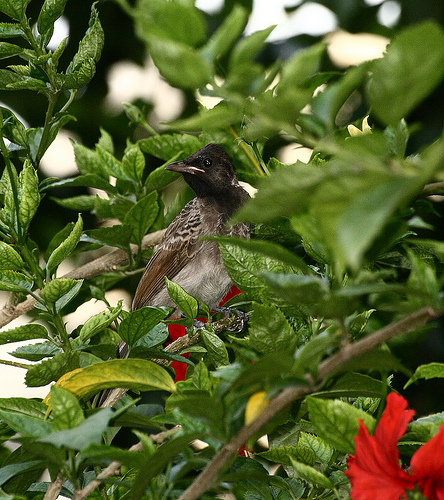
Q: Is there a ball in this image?
A: No, there are no balls.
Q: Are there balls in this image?
A: No, there are no balls.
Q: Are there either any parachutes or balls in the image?
A: No, there are no balls or parachutes.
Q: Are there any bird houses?
A: No, there are no bird houses.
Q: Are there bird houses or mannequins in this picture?
A: No, there are no bird houses or mannequins.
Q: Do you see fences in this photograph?
A: No, there are no fences.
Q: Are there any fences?
A: No, there are no fences.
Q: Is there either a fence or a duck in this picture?
A: No, there are no fences or ducks.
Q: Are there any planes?
A: No, there are no planes.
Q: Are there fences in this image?
A: No, there are no fences.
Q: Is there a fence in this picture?
A: No, there are no fences.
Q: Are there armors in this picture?
A: No, there are no armors.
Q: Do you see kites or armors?
A: No, there are no armors or kites.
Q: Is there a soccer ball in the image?
A: No, there are no soccer balls.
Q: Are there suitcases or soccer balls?
A: No, there are no soccer balls or suitcases.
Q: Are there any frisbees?
A: No, there are no frisbees.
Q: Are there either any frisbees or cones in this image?
A: No, there are no frisbees or cones.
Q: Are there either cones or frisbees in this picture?
A: No, there are no frisbees or cones.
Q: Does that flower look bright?
A: Yes, the flower is bright.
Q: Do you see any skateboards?
A: No, there are no skateboards.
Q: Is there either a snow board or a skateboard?
A: No, there are no skateboards or snowboards.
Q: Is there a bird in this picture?
A: Yes, there is a bird.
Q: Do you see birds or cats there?
A: Yes, there is a bird.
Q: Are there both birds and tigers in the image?
A: No, there is a bird but no tigers.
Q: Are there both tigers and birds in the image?
A: No, there is a bird but no tigers.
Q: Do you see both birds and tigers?
A: No, there is a bird but no tigers.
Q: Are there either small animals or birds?
A: Yes, there is a small bird.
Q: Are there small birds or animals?
A: Yes, there is a small bird.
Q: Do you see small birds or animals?
A: Yes, there is a small bird.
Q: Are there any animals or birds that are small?
A: Yes, the bird is small.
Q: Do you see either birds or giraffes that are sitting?
A: Yes, the bird is sitting.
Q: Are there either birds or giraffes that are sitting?
A: Yes, the bird is sitting.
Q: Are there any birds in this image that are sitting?
A: Yes, there is a bird that is sitting.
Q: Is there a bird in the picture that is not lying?
A: Yes, there is a bird that is sitting.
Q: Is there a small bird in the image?
A: Yes, there is a small bird.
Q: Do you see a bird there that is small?
A: Yes, there is a bird that is small.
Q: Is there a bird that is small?
A: Yes, there is a bird that is small.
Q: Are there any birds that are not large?
A: Yes, there is a small bird.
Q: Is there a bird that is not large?
A: Yes, there is a small bird.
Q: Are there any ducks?
A: No, there are no ducks.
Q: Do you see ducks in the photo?
A: No, there are no ducks.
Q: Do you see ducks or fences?
A: No, there are no ducks or fences.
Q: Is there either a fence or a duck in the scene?
A: No, there are no ducks or fences.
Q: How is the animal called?
A: The animal is a bird.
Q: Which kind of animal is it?
A: The animal is a bird.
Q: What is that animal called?
A: This is a bird.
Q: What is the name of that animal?
A: This is a bird.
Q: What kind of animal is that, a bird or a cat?
A: This is a bird.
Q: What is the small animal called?
A: The animal is a bird.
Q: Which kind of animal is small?
A: The animal is a bird.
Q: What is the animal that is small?
A: The animal is a bird.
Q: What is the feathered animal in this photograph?
A: The animal is a bird.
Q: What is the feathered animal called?
A: The animal is a bird.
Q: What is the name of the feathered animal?
A: The animal is a bird.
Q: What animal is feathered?
A: The animal is a bird.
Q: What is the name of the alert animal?
A: The animal is a bird.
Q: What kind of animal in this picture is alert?
A: The animal is a bird.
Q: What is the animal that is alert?
A: The animal is a bird.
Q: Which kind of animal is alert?
A: The animal is a bird.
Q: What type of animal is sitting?
A: The animal is a bird.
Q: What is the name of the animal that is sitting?
A: The animal is a bird.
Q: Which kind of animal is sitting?
A: The animal is a bird.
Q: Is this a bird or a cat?
A: This is a bird.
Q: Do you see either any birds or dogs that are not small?
A: No, there is a bird but it is small.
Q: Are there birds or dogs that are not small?
A: No, there is a bird but it is small.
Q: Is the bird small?
A: Yes, the bird is small.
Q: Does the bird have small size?
A: Yes, the bird is small.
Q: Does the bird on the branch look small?
A: Yes, the bird is small.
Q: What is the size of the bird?
A: The bird is small.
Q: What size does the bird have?
A: The bird has small size.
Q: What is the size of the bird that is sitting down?
A: The bird is small.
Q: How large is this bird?
A: The bird is small.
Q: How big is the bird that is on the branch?
A: The bird is small.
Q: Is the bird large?
A: No, the bird is small.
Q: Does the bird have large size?
A: No, the bird is small.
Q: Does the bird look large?
A: No, the bird is small.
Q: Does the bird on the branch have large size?
A: No, the bird is small.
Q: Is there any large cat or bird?
A: No, there is a bird but it is small.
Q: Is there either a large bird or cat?
A: No, there is a bird but it is small.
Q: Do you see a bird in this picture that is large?
A: No, there is a bird but it is small.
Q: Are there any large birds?
A: No, there is a bird but it is small.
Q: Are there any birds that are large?
A: No, there is a bird but it is small.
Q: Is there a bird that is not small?
A: No, there is a bird but it is small.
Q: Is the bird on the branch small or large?
A: The bird is small.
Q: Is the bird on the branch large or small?
A: The bird is small.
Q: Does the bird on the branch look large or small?
A: The bird is small.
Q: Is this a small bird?
A: Yes, this is a small bird.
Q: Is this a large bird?
A: No, this is a small bird.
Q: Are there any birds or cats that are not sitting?
A: No, there is a bird but it is sitting.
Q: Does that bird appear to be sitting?
A: Yes, the bird is sitting.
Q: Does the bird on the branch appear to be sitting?
A: Yes, the bird is sitting.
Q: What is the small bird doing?
A: The bird is sitting.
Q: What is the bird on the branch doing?
A: The bird is sitting.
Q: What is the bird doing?
A: The bird is sitting.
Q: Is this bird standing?
A: No, the bird is sitting.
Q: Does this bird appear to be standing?
A: No, the bird is sitting.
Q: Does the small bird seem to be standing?
A: No, the bird is sitting.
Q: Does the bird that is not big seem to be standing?
A: No, the bird is sitting.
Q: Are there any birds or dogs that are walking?
A: No, there is a bird but it is sitting.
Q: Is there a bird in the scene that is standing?
A: No, there is a bird but it is sitting.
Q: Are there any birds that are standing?
A: No, there is a bird but it is sitting.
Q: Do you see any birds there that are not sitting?
A: No, there is a bird but it is sitting.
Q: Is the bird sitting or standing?
A: The bird is sitting.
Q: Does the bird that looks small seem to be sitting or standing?
A: The bird is sitting.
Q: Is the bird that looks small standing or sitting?
A: The bird is sitting.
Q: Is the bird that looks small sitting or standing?
A: The bird is sitting.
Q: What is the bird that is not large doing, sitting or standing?
A: The bird is sitting.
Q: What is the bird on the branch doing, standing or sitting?
A: The bird is sitting.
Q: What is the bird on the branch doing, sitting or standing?
A: The bird is sitting.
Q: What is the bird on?
A: The bird is on the branch.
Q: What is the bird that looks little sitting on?
A: The bird is sitting on the plant.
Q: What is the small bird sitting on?
A: The bird is sitting on the plant.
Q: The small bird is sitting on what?
A: The bird is sitting on the plant.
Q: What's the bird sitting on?
A: The bird is sitting on the plant.